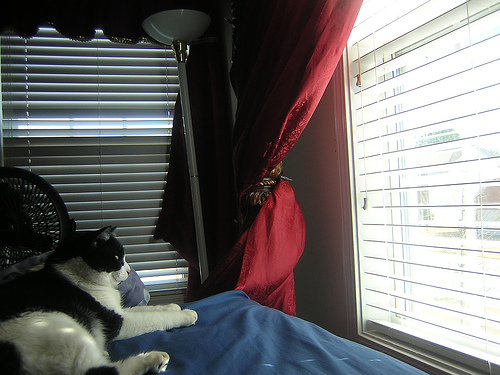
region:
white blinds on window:
[346, 2, 487, 320]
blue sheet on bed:
[157, 296, 355, 372]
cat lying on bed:
[19, 239, 181, 373]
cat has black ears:
[65, 217, 128, 249]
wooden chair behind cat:
[2, 169, 67, 257]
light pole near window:
[148, 2, 223, 294]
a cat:
[6, 231, 168, 373]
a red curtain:
[247, 220, 297, 274]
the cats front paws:
[163, 296, 198, 326]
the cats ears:
[96, 222, 119, 241]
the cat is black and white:
[6, 226, 168, 373]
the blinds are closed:
[36, 56, 126, 109]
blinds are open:
[51, 119, 113, 136]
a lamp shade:
[156, 14, 201, 31]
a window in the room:
[350, 5, 497, 340]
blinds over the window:
[350, 10, 490, 350]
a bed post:
[226, 5, 321, 320]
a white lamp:
[146, 7, 237, 298]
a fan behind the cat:
[6, 170, 63, 255]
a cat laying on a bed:
[5, 235, 186, 370]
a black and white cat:
[15, 230, 189, 373]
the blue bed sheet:
[186, 300, 371, 370]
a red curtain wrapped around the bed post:
[230, 20, 295, 310]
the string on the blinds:
[348, 58, 365, 86]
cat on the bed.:
[1, 213, 202, 374]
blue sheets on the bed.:
[106, 283, 424, 373]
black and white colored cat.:
[0, 220, 202, 372]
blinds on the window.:
[0, 26, 187, 295]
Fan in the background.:
[0, 157, 80, 274]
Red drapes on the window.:
[202, 0, 368, 328]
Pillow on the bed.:
[0, 237, 157, 311]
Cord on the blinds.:
[349, 43, 380, 215]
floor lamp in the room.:
[142, 5, 214, 295]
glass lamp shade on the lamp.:
[136, 8, 213, 49]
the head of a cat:
[48, 214, 150, 310]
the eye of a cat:
[103, 234, 153, 267]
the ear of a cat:
[76, 208, 134, 258]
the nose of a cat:
[106, 250, 153, 290]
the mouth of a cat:
[113, 252, 157, 290]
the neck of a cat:
[44, 231, 99, 295]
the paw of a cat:
[147, 287, 198, 344]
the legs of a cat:
[114, 276, 221, 348]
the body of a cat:
[18, 189, 155, 356]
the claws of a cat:
[158, 286, 210, 340]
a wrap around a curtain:
[244, 161, 285, 210]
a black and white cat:
[1, 215, 194, 373]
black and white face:
[67, 235, 123, 273]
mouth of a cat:
[110, 261, 131, 292]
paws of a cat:
[164, 300, 194, 324]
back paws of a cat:
[140, 344, 175, 374]